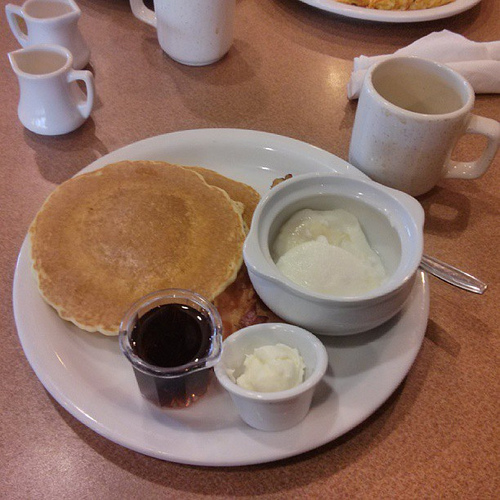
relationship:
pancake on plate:
[24, 153, 263, 341] [6, 123, 436, 476]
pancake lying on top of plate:
[27, 157, 248, 339] [6, 123, 436, 476]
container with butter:
[218, 322, 328, 431] [239, 343, 304, 393]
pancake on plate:
[27, 160, 249, 338] [6, 123, 436, 476]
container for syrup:
[118, 286, 225, 410] [133, 303, 208, 406]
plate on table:
[6, 123, 436, 476] [0, 1, 483, 497]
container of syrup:
[118, 286, 225, 410] [136, 297, 215, 405]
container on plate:
[118, 286, 225, 410] [6, 123, 436, 476]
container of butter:
[210, 322, 326, 431] [229, 339, 307, 409]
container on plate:
[210, 322, 326, 431] [6, 123, 436, 476]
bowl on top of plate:
[237, 169, 430, 339] [12, 96, 465, 489]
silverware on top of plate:
[423, 249, 487, 316] [16, 112, 444, 492]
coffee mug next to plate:
[344, 35, 498, 212] [6, 123, 436, 476]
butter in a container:
[227, 343, 307, 393] [210, 322, 326, 431]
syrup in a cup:
[132, 309, 212, 366] [114, 284, 224, 414]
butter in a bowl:
[244, 344, 297, 382] [254, 397, 285, 427]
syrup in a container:
[132, 309, 212, 366] [118, 286, 225, 410]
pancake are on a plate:
[27, 160, 249, 338] [339, 353, 403, 403]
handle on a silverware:
[421, 258, 451, 278] [417, 255, 486, 294]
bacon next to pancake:
[193, 172, 296, 401] [27, 160, 249, 338]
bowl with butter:
[237, 169, 430, 339] [271, 206, 395, 300]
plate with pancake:
[6, 123, 436, 476] [27, 160, 249, 338]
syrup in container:
[132, 309, 212, 366] [118, 286, 225, 410]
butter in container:
[227, 343, 307, 393] [210, 318, 333, 438]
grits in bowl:
[266, 202, 391, 297] [237, 169, 430, 339]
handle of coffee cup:
[442, 111, 483, 185] [345, 52, 484, 210]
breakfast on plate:
[25, 154, 430, 437] [6, 123, 436, 476]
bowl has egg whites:
[237, 169, 430, 339] [270, 205, 389, 299]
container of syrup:
[118, 286, 225, 410] [132, 309, 212, 366]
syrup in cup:
[132, 309, 212, 366] [114, 284, 224, 414]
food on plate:
[29, 156, 251, 340] [6, 123, 436, 476]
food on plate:
[23, 156, 244, 332] [6, 123, 436, 476]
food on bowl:
[269, 194, 380, 288] [237, 164, 424, 331]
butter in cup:
[227, 343, 307, 393] [217, 314, 327, 433]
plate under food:
[6, 123, 436, 476] [34, 159, 281, 339]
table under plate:
[0, 1, 483, 497] [6, 123, 436, 476]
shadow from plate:
[62, 376, 393, 497] [6, 123, 436, 476]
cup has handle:
[7, 42, 98, 136] [63, 64, 96, 122]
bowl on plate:
[237, 169, 430, 339] [6, 123, 436, 476]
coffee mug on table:
[344, 53, 499, 212] [0, 1, 483, 497]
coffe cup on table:
[124, 0, 242, 72] [0, 1, 483, 497]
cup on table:
[6, 42, 98, 136] [0, 1, 483, 497]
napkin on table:
[340, 25, 493, 105] [0, 1, 483, 497]